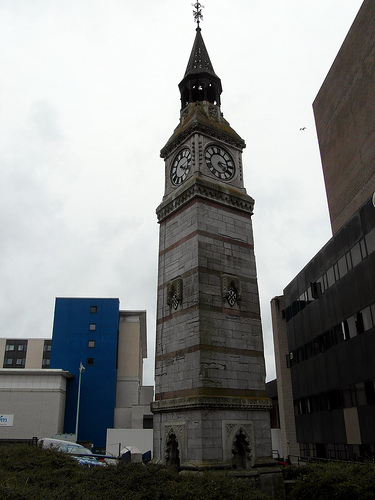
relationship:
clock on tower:
[204, 147, 235, 179] [151, 7, 278, 475]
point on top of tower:
[190, 0, 205, 32] [117, 1, 287, 390]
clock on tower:
[204, 143, 235, 180] [145, 14, 285, 485]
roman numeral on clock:
[213, 145, 223, 157] [196, 130, 246, 189]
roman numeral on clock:
[221, 147, 225, 156] [196, 130, 246, 189]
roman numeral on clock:
[223, 155, 233, 162] [196, 130, 246, 189]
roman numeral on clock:
[226, 162, 236, 170] [196, 130, 246, 189]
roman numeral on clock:
[206, 166, 218, 177] [196, 130, 246, 189]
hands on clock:
[206, 154, 254, 180] [204, 143, 235, 180]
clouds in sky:
[258, 172, 316, 235] [211, 2, 325, 258]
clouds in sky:
[24, 98, 71, 153] [4, 5, 156, 296]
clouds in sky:
[1, 0, 199, 337] [4, 5, 156, 296]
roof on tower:
[169, 78, 240, 140] [140, 38, 276, 488]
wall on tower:
[154, 192, 277, 432] [145, 14, 285, 485]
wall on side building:
[47, 293, 122, 448] [51, 290, 146, 455]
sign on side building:
[0, 413, 18, 427] [0, 356, 82, 452]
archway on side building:
[214, 418, 267, 471] [154, 2, 278, 467]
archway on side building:
[221, 419, 255, 470] [144, 0, 285, 465]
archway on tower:
[221, 419, 255, 470] [151, 7, 278, 475]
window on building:
[332, 320, 348, 341] [244, 70, 371, 475]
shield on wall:
[225, 288, 236, 306] [190, 124, 275, 469]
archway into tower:
[159, 428, 181, 468] [128, 19, 294, 488]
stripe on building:
[146, 384, 270, 403] [144, 0, 273, 485]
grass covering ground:
[2, 443, 373, 498] [1, 441, 372, 497]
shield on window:
[227, 288, 237, 306] [222, 274, 241, 307]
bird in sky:
[297, 125, 309, 134] [2, 4, 369, 388]